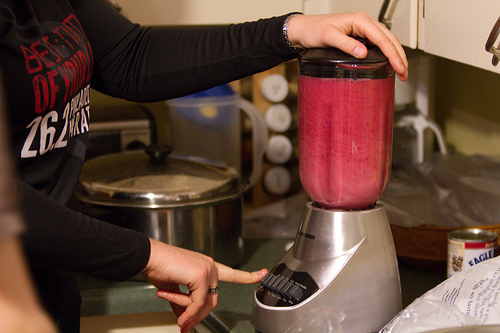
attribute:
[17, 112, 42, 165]
white lettering — RED